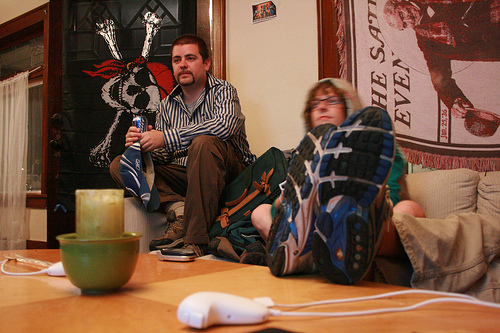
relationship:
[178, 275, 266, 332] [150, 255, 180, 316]
controller on table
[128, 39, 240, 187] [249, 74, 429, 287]
man with person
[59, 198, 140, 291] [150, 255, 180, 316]
bowl on table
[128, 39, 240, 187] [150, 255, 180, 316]
man near table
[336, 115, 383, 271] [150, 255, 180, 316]
sneakers on table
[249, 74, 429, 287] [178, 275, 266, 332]
person near controller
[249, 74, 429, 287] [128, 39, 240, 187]
person next to man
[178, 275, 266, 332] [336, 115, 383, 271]
controller near sneakers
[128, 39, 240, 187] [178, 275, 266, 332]
man near controller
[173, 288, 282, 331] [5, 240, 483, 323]
controller on surface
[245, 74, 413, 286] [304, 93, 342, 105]
person wearing glasses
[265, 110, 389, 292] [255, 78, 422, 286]
feet of person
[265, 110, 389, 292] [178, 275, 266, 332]
feet near controller